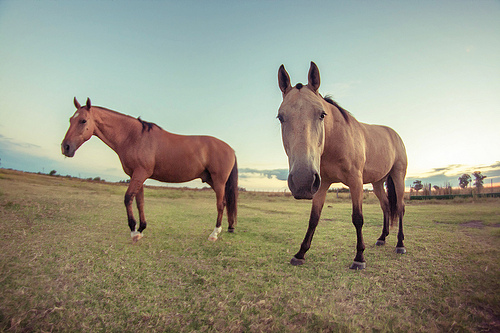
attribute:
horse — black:
[252, 52, 439, 276]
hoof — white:
[207, 234, 219, 241]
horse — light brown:
[279, 70, 480, 255]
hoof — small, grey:
[338, 247, 388, 279]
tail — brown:
[224, 155, 237, 227]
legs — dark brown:
[278, 181, 435, 280]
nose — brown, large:
[286, 169, 323, 199]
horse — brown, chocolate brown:
[60, 95, 240, 242]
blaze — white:
[68, 100, 85, 123]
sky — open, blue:
[93, 15, 262, 93]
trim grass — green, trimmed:
[4, 169, 497, 331]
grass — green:
[1, 167, 499, 332]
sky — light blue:
[2, 1, 499, 192]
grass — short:
[145, 240, 287, 285]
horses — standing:
[276, 60, 406, 268]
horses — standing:
[61, 96, 239, 248]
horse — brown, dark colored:
[61, 100, 252, 233]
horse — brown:
[50, 87, 265, 263]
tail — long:
[228, 145, 255, 229]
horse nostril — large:
[312, 171, 324, 192]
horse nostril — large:
[277, 173, 293, 193]